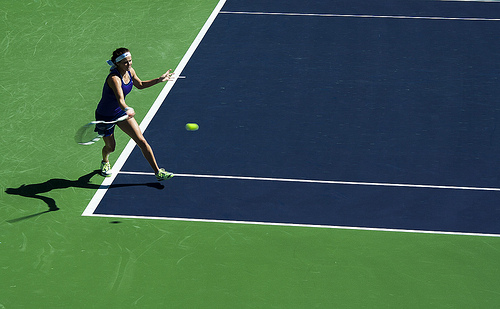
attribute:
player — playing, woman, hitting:
[93, 45, 173, 179]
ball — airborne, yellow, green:
[184, 121, 201, 131]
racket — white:
[72, 115, 134, 147]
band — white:
[109, 52, 134, 62]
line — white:
[215, 3, 498, 30]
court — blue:
[3, 3, 499, 308]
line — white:
[114, 162, 499, 201]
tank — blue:
[103, 72, 139, 107]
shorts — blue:
[95, 113, 130, 133]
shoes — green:
[98, 159, 174, 182]